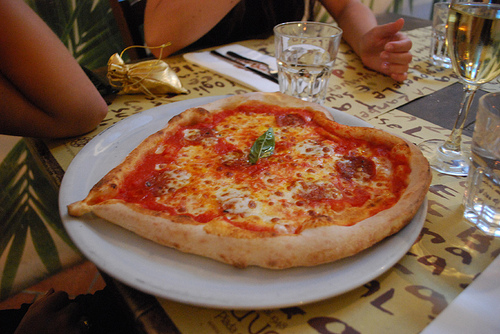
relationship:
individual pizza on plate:
[66, 91, 431, 270] [59, 94, 428, 311]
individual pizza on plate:
[64, 95, 433, 269] [59, 94, 428, 311]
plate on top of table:
[52, 85, 448, 317] [65, 11, 498, 331]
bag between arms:
[106, 37, 193, 93] [13, 7, 230, 137]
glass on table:
[466, 95, 498, 238] [18, 9, 498, 331]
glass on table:
[270, 18, 345, 105] [18, 9, 498, 331]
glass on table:
[427, 0, 459, 68] [18, 9, 498, 331]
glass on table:
[418, 2, 498, 174] [18, 9, 498, 331]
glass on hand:
[270, 18, 345, 105] [360, 16, 414, 82]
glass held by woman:
[270, 18, 345, 105] [123, 0, 418, 85]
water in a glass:
[466, 137, 498, 233] [456, 94, 498, 243]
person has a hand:
[141, 2, 413, 85] [362, 14, 417, 76]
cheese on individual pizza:
[226, 184, 264, 216] [66, 91, 431, 270]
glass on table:
[418, 2, 498, 174] [96, 27, 498, 328]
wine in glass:
[450, 6, 494, 81] [418, 2, 498, 174]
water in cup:
[280, 45, 325, 102] [269, 17, 341, 102]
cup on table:
[269, 17, 341, 102] [119, 12, 496, 327]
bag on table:
[107, 42, 189, 99] [18, 9, 498, 331]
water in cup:
[463, 139, 498, 236] [465, 86, 498, 230]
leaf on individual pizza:
[247, 124, 278, 164] [66, 91, 431, 270]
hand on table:
[360, 18, 412, 82] [18, 9, 498, 331]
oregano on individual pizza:
[247, 120, 277, 165] [66, 91, 431, 270]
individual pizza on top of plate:
[66, 91, 431, 270] [59, 94, 428, 311]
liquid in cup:
[275, 43, 339, 101] [269, 24, 327, 82]